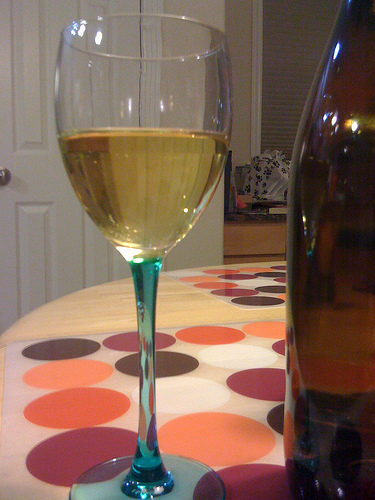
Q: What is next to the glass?
A: A bottle.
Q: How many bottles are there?
A: One.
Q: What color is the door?
A: White.